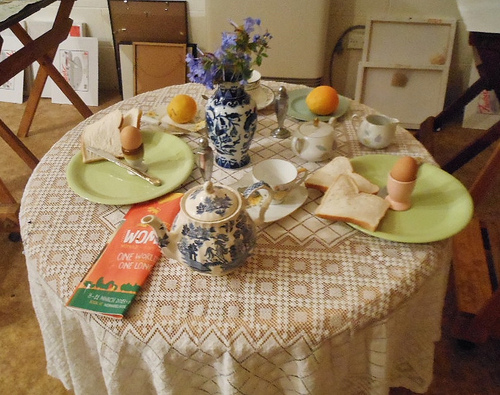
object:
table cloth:
[18, 79, 454, 395]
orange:
[167, 94, 197, 123]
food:
[67, 83, 421, 229]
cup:
[250, 159, 307, 204]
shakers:
[205, 85, 258, 168]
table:
[16, 80, 451, 395]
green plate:
[343, 154, 475, 242]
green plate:
[67, 129, 193, 205]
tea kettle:
[140, 181, 275, 277]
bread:
[304, 155, 380, 195]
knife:
[85, 146, 161, 186]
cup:
[384, 172, 416, 211]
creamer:
[351, 114, 400, 149]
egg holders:
[121, 143, 148, 176]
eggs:
[389, 156, 417, 181]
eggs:
[119, 125, 142, 150]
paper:
[65, 193, 184, 319]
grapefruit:
[305, 85, 340, 115]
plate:
[285, 89, 348, 122]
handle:
[242, 182, 272, 226]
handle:
[295, 168, 307, 188]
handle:
[292, 136, 305, 156]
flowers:
[183, 17, 273, 91]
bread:
[314, 174, 390, 233]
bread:
[81, 107, 144, 164]